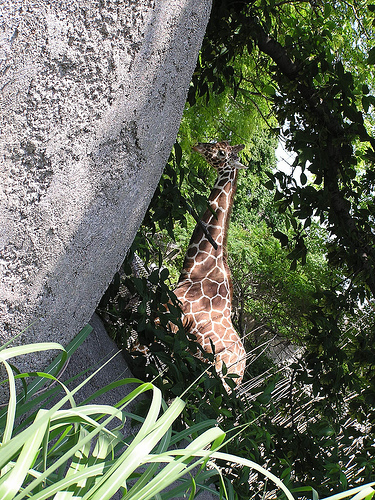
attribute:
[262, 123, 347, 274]
leaves — green, thin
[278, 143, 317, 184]
sky — light, blue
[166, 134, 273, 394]
giraffe — standing, grazing, brown, white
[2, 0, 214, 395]
cement — chipped, gray, large, light, grey, textured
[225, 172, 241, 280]
mane — brown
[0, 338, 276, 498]
grass — light, gray, green, tall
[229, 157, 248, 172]
ear — white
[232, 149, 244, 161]
horn — small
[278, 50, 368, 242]
trees — green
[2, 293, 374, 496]
weeds — green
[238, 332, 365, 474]
plant — white